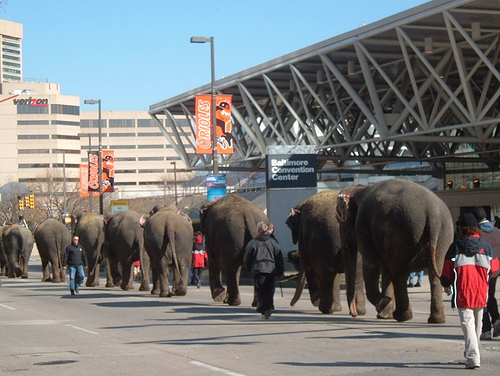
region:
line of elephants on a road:
[2, 175, 452, 326]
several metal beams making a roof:
[148, 0, 495, 174]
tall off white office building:
[1, 78, 83, 213]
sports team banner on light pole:
[193, 91, 233, 155]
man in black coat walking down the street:
[62, 235, 89, 296]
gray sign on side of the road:
[263, 143, 324, 271]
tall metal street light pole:
[83, 98, 104, 220]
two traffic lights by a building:
[443, 177, 480, 189]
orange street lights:
[16, 191, 36, 213]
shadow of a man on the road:
[273, 358, 465, 371]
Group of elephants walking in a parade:
[0, 179, 455, 326]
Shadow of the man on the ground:
[267, 359, 470, 371]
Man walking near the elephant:
[439, 209, 499, 369]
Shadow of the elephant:
[87, 298, 224, 308]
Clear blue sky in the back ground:
[0, 0, 433, 110]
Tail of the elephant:
[164, 220, 184, 276]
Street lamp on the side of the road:
[83, 97, 103, 213]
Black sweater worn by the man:
[242, 233, 284, 276]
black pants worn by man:
[252, 271, 277, 312]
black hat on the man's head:
[455, 211, 480, 227]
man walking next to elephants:
[243, 222, 285, 319]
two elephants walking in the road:
[288, 178, 458, 323]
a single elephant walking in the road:
[138, 206, 194, 296]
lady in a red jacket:
[440, 212, 498, 369]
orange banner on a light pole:
[193, 94, 233, 156]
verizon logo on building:
[10, 96, 46, 106]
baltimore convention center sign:
[264, 154, 318, 187]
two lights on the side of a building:
[443, 178, 481, 188]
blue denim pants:
[68, 264, 85, 294]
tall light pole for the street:
[188, 34, 218, 224]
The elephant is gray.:
[1, 218, 35, 286]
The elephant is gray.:
[31, 208, 76, 291]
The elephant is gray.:
[67, 206, 119, 295]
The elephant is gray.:
[94, 206, 155, 295]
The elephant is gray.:
[133, 195, 196, 302]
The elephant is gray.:
[194, 185, 284, 311]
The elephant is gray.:
[281, 181, 366, 322]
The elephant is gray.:
[328, 175, 460, 335]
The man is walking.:
[51, 228, 126, 310]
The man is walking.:
[424, 205, 499, 372]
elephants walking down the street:
[5, 175, 461, 325]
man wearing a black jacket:
[59, 228, 101, 296]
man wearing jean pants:
[47, 223, 97, 309]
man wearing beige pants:
[440, 202, 490, 372]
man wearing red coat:
[422, 198, 494, 365]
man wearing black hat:
[420, 205, 495, 365]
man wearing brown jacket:
[465, 203, 497, 335]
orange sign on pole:
[192, 85, 235, 162]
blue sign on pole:
[204, 173, 231, 204]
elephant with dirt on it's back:
[282, 173, 364, 322]